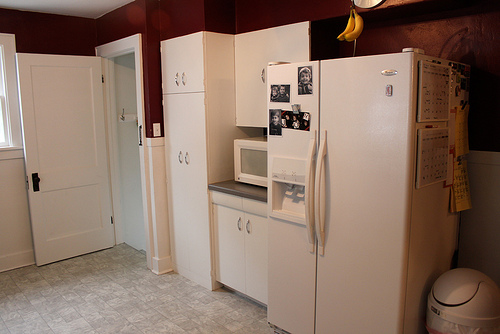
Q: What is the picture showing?
A: It is showing a kitchen.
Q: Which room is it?
A: It is a kitchen.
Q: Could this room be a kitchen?
A: Yes, it is a kitchen.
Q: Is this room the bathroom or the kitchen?
A: It is the kitchen.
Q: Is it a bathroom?
A: No, it is a kitchen.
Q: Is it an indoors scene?
A: Yes, it is indoors.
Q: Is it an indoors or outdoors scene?
A: It is indoors.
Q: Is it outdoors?
A: No, it is indoors.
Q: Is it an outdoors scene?
A: No, it is indoors.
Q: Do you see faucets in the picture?
A: No, there are no faucets.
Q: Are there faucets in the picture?
A: No, there are no faucets.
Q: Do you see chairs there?
A: No, there are no chairs.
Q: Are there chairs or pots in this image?
A: No, there are no chairs or pots.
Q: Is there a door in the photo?
A: Yes, there are doors.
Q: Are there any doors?
A: Yes, there are doors.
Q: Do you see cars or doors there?
A: Yes, there are doors.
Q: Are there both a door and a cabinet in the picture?
A: Yes, there are both a door and a cabinet.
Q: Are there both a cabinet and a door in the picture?
A: Yes, there are both a door and a cabinet.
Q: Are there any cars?
A: No, there are no cars.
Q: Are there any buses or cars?
A: No, there are no cars or buses.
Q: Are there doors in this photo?
A: Yes, there is a door.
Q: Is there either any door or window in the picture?
A: Yes, there is a door.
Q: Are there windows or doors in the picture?
A: Yes, there is a door.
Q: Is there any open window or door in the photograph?
A: Yes, there is an open door.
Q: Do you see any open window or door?
A: Yes, there is an open door.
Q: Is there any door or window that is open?
A: Yes, the door is open.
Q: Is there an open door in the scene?
A: Yes, there is an open door.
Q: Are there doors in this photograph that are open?
A: Yes, there is a door that is open.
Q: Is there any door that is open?
A: Yes, there is a door that is open.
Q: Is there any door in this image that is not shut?
A: Yes, there is a open door.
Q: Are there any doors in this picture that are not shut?
A: Yes, there is a open door.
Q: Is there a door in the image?
A: Yes, there is a door.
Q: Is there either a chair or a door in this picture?
A: Yes, there is a door.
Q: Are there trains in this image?
A: No, there are no trains.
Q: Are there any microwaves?
A: Yes, there is a microwave.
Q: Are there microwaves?
A: Yes, there is a microwave.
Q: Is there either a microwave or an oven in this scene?
A: Yes, there is a microwave.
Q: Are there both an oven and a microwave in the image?
A: No, there is a microwave but no ovens.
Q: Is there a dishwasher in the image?
A: No, there are no dishwashers.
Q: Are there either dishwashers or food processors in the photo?
A: No, there are no dishwashers or food processors.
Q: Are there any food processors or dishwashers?
A: No, there are no dishwashers or food processors.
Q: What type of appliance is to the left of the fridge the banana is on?
A: The appliance is a microwave.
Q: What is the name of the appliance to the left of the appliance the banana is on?
A: The appliance is a microwave.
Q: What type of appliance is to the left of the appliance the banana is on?
A: The appliance is a microwave.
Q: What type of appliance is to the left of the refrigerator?
A: The appliance is a microwave.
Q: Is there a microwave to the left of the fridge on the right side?
A: Yes, there is a microwave to the left of the freezer.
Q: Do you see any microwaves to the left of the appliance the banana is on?
A: Yes, there is a microwave to the left of the freezer.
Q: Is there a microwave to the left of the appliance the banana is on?
A: Yes, there is a microwave to the left of the freezer.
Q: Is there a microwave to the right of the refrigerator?
A: No, the microwave is to the left of the refrigerator.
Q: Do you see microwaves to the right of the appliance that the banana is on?
A: No, the microwave is to the left of the refrigerator.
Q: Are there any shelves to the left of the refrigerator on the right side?
A: No, there is a microwave to the left of the freezer.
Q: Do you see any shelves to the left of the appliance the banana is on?
A: No, there is a microwave to the left of the freezer.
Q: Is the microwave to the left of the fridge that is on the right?
A: Yes, the microwave is to the left of the refrigerator.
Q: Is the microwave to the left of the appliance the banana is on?
A: Yes, the microwave is to the left of the refrigerator.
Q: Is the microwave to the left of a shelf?
A: No, the microwave is to the left of the refrigerator.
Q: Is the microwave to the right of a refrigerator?
A: No, the microwave is to the left of a refrigerator.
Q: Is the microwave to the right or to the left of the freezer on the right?
A: The microwave is to the left of the refrigerator.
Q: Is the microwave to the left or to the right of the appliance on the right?
A: The microwave is to the left of the refrigerator.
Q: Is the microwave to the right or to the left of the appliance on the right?
A: The microwave is to the left of the refrigerator.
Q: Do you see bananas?
A: Yes, there is a banana.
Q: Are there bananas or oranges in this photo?
A: Yes, there is a banana.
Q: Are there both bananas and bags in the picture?
A: No, there is a banana but no bags.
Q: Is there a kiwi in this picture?
A: No, there are no kiwis.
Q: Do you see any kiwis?
A: No, there are no kiwis.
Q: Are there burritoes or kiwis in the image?
A: No, there are no kiwis or burritoes.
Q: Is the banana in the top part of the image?
A: Yes, the banana is in the top of the image.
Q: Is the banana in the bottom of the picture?
A: No, the banana is in the top of the image.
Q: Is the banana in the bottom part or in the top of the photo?
A: The banana is in the top of the image.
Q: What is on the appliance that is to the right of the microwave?
A: The banana is on the refrigerator.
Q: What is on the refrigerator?
A: The banana is on the refrigerator.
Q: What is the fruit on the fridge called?
A: The fruit is a banana.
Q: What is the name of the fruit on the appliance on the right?
A: The fruit is a banana.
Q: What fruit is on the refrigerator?
A: The fruit is a banana.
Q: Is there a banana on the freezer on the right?
A: Yes, there is a banana on the freezer.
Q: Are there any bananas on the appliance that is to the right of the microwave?
A: Yes, there is a banana on the freezer.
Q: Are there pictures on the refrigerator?
A: No, there is a banana on the refrigerator.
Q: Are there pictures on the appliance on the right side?
A: No, there is a banana on the refrigerator.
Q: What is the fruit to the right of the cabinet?
A: The fruit is a banana.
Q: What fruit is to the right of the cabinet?
A: The fruit is a banana.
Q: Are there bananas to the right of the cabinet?
A: Yes, there is a banana to the right of the cabinet.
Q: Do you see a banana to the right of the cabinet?
A: Yes, there is a banana to the right of the cabinet.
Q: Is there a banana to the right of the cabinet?
A: Yes, there is a banana to the right of the cabinet.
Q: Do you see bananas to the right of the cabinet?
A: Yes, there is a banana to the right of the cabinet.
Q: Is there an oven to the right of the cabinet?
A: No, there is a banana to the right of the cabinet.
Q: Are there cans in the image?
A: Yes, there is a can.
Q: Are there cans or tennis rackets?
A: Yes, there is a can.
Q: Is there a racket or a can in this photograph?
A: Yes, there is a can.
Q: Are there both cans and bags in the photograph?
A: No, there is a can but no bags.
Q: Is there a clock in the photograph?
A: No, there are no clocks.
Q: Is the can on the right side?
A: Yes, the can is on the right of the image.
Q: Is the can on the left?
A: No, the can is on the right of the image.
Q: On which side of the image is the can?
A: The can is on the right of the image.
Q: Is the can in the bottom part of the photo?
A: Yes, the can is in the bottom of the image.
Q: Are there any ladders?
A: No, there are no ladders.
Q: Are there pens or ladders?
A: No, there are no ladders or pens.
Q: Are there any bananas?
A: Yes, there are bananas.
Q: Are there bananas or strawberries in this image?
A: Yes, there are bananas.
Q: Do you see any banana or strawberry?
A: Yes, there are bananas.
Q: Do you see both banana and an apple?
A: No, there are bananas but no apples.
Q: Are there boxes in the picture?
A: No, there are no boxes.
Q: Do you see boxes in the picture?
A: No, there are no boxes.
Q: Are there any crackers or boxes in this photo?
A: No, there are no boxes or crackers.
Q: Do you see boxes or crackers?
A: No, there are no boxes or crackers.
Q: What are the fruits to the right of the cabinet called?
A: The fruits are bananas.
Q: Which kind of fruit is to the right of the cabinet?
A: The fruits are bananas.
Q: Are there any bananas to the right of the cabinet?
A: Yes, there are bananas to the right of the cabinet.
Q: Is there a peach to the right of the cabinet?
A: No, there are bananas to the right of the cabinet.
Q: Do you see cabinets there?
A: Yes, there is a cabinet.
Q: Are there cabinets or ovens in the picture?
A: Yes, there is a cabinet.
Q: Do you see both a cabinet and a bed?
A: No, there is a cabinet but no beds.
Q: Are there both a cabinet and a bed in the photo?
A: No, there is a cabinet but no beds.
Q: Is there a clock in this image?
A: No, there are no clocks.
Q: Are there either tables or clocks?
A: No, there are no clocks or tables.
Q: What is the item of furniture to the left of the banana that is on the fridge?
A: The piece of furniture is a cabinet.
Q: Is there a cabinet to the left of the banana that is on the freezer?
A: Yes, there is a cabinet to the left of the banana.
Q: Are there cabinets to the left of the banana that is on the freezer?
A: Yes, there is a cabinet to the left of the banana.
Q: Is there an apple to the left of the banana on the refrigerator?
A: No, there is a cabinet to the left of the banana.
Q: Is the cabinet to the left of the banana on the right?
A: Yes, the cabinet is to the left of the banana.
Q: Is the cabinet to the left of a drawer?
A: No, the cabinet is to the left of the banana.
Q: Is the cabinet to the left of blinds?
A: No, the cabinet is to the left of the bananas.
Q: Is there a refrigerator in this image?
A: Yes, there is a refrigerator.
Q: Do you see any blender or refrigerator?
A: Yes, there is a refrigerator.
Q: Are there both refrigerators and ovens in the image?
A: No, there is a refrigerator but no ovens.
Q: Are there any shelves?
A: No, there are no shelves.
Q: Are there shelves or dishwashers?
A: No, there are no shelves or dishwashers.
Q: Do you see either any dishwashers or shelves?
A: No, there are no shelves or dishwashers.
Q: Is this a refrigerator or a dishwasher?
A: This is a refrigerator.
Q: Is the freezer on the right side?
A: Yes, the freezer is on the right of the image.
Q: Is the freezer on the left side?
A: No, the freezer is on the right of the image.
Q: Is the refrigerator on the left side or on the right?
A: The refrigerator is on the right of the image.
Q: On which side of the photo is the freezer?
A: The freezer is on the right of the image.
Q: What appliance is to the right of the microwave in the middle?
A: The appliance is a refrigerator.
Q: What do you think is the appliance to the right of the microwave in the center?
A: The appliance is a refrigerator.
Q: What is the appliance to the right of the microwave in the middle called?
A: The appliance is a refrigerator.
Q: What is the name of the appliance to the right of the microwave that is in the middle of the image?
A: The appliance is a refrigerator.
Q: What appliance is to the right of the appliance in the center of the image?
A: The appliance is a refrigerator.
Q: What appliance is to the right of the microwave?
A: The appliance is a refrigerator.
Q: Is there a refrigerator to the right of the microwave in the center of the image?
A: Yes, there is a refrigerator to the right of the microwave.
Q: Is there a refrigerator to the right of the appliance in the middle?
A: Yes, there is a refrigerator to the right of the microwave.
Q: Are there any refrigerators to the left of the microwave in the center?
A: No, the refrigerator is to the right of the microwave.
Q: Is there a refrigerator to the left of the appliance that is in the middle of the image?
A: No, the refrigerator is to the right of the microwave.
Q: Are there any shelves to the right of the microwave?
A: No, there is a refrigerator to the right of the microwave.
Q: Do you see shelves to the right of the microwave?
A: No, there is a refrigerator to the right of the microwave.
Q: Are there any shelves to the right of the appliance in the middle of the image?
A: No, there is a refrigerator to the right of the microwave.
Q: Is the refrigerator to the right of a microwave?
A: Yes, the refrigerator is to the right of a microwave.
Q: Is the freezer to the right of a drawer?
A: No, the freezer is to the right of a microwave.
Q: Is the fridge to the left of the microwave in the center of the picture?
A: No, the fridge is to the right of the microwave.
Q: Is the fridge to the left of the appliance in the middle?
A: No, the fridge is to the right of the microwave.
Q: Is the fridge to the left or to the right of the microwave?
A: The fridge is to the right of the microwave.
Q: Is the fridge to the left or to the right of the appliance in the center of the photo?
A: The fridge is to the right of the microwave.